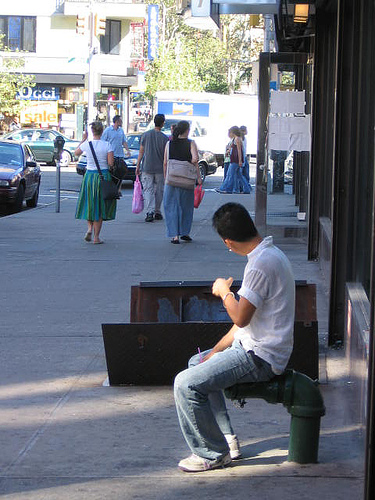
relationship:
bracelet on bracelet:
[220, 289, 235, 308] [222, 290, 234, 308]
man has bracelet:
[171, 200, 295, 471] [220, 289, 235, 308]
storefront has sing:
[7, 75, 130, 150] [23, 72, 122, 158]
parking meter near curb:
[52, 135, 65, 212] [3, 192, 75, 241]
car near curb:
[1, 141, 41, 213] [7, 203, 54, 221]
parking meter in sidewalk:
[49, 133, 67, 212] [1, 183, 353, 497]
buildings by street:
[1, 2, 279, 150] [45, 161, 294, 240]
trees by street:
[140, 11, 257, 99] [45, 161, 294, 240]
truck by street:
[150, 85, 261, 162] [45, 161, 294, 240]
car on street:
[1, 141, 41, 213] [27, 146, 78, 210]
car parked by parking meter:
[1, 141, 41, 213] [52, 135, 65, 212]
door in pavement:
[129, 279, 318, 324] [0, 181, 374, 498]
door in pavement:
[98, 321, 321, 388] [0, 181, 374, 498]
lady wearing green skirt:
[72, 117, 127, 246] [67, 165, 122, 246]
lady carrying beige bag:
[161, 121, 204, 245] [166, 158, 197, 188]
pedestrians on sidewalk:
[132, 113, 170, 222] [1, 183, 353, 497]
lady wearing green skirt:
[72, 117, 127, 246] [74, 169, 117, 222]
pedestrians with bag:
[74, 112, 249, 242] [87, 144, 119, 200]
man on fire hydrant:
[171, 200, 295, 471] [222, 367, 328, 464]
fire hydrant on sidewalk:
[223, 361, 325, 469] [1, 183, 353, 497]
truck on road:
[150, 85, 261, 162] [1, 148, 295, 217]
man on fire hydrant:
[171, 200, 295, 471] [223, 361, 325, 469]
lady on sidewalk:
[72, 117, 129, 246] [0, 176, 341, 436]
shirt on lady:
[80, 139, 113, 170] [74, 120, 120, 244]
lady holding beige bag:
[161, 121, 204, 245] [165, 158, 199, 186]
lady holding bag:
[72, 117, 127, 246] [87, 138, 124, 200]